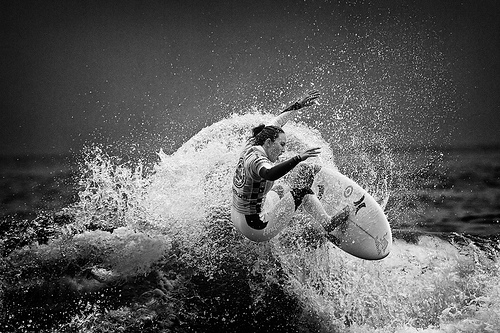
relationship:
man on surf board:
[226, 107, 332, 250] [283, 165, 393, 260]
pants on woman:
[259, 185, 334, 245] [233, 95, 354, 244]